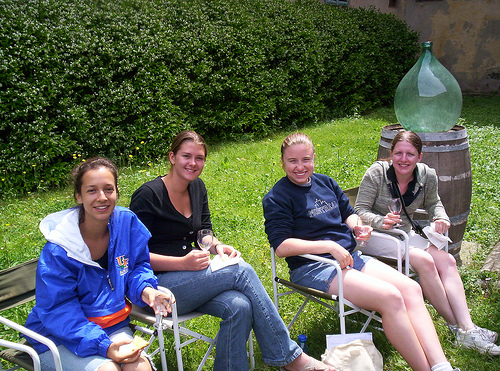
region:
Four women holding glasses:
[5, 103, 498, 369]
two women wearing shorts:
[263, 119, 498, 369]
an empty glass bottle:
[364, 30, 484, 133]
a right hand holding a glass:
[185, 222, 221, 278]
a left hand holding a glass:
[128, 272, 187, 340]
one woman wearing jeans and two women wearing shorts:
[140, 91, 495, 369]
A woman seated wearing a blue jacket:
[9, 155, 176, 370]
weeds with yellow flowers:
[121, 133, 153, 178]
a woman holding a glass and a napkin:
[355, 109, 497, 369]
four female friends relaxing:
[5, 34, 497, 366]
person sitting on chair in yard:
[42, 151, 167, 368]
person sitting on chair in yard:
[291, 135, 346, 304]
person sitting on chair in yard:
[362, 132, 455, 297]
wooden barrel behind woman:
[375, 110, 492, 253]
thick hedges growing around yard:
[11, 2, 463, 124]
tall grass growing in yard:
[151, 124, 496, 369]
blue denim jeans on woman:
[205, 272, 267, 364]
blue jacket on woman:
[25, 205, 153, 335]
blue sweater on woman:
[253, 176, 368, 272]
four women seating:
[7, 107, 488, 367]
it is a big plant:
[7, 6, 357, 126]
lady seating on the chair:
[267, 227, 439, 369]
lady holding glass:
[184, 223, 219, 265]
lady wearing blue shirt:
[244, 173, 370, 269]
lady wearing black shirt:
[130, 173, 223, 274]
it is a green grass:
[221, 143, 252, 240]